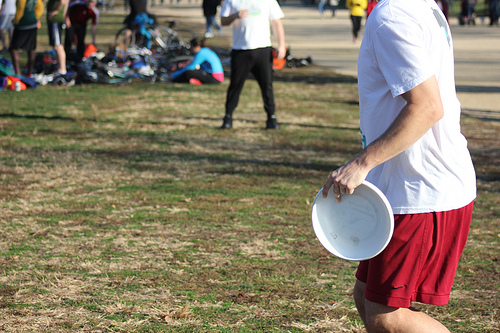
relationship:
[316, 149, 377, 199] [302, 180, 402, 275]
hand grasping a frisbee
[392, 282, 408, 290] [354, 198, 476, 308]
black logo on shorts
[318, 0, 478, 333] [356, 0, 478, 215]
man wearing white shirt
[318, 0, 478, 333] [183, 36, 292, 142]
man wearing black pants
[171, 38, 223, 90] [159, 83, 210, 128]
woman sitting on ground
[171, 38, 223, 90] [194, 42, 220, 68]
woman wearing blue top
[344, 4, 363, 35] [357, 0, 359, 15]
jogger wearing a yellow jacket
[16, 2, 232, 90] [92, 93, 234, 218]
crowd of people at a park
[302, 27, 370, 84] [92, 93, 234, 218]
paved pathway in a park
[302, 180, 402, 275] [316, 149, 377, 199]
holding a frisbee in hand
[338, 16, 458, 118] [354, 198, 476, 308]
man has shorts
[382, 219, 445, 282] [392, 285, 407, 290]
shorts with black logo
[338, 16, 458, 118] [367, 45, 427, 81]
man has white shirt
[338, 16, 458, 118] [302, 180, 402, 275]
man are playing frisbee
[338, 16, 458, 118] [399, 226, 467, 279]
man in red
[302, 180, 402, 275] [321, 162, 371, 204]
frisbee in mans hand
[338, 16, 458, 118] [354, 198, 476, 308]
man wearing shorts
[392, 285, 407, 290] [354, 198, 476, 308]
black logo on shorts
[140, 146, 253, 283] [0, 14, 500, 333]
green grass in ground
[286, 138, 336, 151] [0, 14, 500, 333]
brown grass in a ground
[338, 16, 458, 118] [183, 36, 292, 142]
man wearing long black pants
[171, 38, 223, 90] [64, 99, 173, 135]
woman sitting on grass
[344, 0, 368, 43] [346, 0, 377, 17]
jogger with yellow jacket